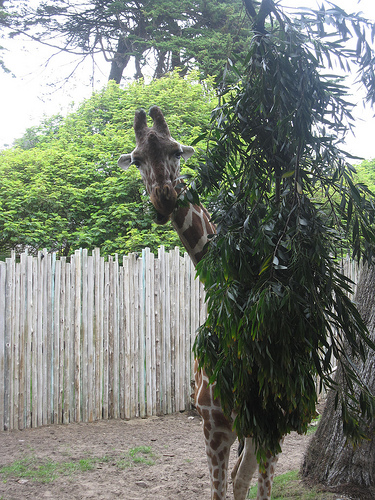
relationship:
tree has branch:
[103, 15, 176, 84] [183, 28, 373, 461]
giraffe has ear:
[113, 103, 292, 498] [172, 141, 193, 158]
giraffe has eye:
[113, 103, 292, 498] [173, 146, 187, 158]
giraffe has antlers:
[113, 103, 292, 498] [149, 105, 172, 135]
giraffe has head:
[113, 103, 292, 498] [116, 106, 196, 224]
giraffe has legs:
[113, 103, 292, 498] [192, 400, 278, 498]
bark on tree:
[108, 34, 131, 82] [1, 0, 262, 83]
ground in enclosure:
[0, 412, 319, 498] [1, 247, 374, 499]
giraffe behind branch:
[113, 103, 292, 498] [195, 0, 374, 473]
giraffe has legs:
[113, 103, 292, 498] [197, 407, 279, 499]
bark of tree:
[294, 236, 371, 498] [103, 15, 176, 84]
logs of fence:
[4, 235, 204, 440] [0, 243, 205, 430]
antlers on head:
[123, 101, 174, 139] [110, 101, 205, 227]